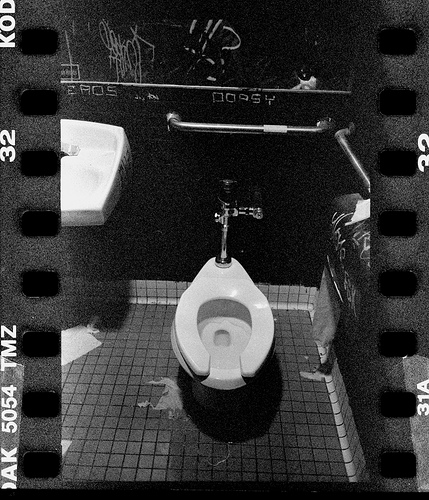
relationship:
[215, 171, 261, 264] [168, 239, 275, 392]
pipe connected to toilet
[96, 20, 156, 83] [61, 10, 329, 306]
graffiti on wall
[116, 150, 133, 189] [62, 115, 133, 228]
graffiti on sink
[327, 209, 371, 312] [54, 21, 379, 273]
graffiti on wall